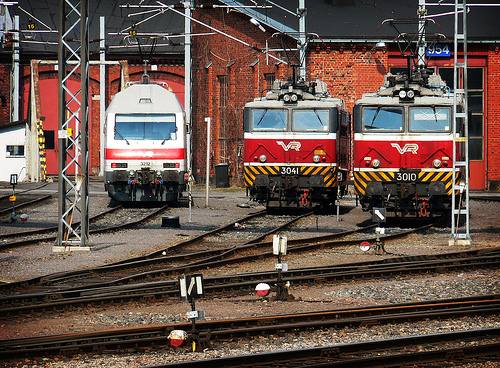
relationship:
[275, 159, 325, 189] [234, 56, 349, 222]
number on train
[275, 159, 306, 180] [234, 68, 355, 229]
number on train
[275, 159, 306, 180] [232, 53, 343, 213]
number on train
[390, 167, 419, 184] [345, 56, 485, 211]
number on train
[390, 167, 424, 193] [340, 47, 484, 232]
number on train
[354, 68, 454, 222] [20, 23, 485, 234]
engine in yard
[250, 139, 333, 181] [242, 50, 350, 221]
lights on train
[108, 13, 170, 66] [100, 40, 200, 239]
wires above train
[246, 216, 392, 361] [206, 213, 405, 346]
tracks on ground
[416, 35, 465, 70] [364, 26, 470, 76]
numbers on wall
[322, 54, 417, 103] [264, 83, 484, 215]
wall behind train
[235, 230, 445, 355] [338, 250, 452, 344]
gravel between tracks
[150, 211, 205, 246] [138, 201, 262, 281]
box on ground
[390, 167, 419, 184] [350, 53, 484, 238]
number on train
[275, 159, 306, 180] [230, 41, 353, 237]
number on train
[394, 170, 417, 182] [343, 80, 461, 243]
white number on train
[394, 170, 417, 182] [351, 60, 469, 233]
white number on train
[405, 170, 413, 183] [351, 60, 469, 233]
white number on train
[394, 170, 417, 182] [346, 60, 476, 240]
white number on train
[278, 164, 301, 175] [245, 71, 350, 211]
white number on train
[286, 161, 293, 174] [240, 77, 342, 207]
white number on train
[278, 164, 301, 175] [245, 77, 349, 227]
white number on train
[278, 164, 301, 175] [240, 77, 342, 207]
white number on train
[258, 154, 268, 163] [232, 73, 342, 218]
headlight on front of train car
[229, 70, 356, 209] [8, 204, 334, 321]
engine on train tracks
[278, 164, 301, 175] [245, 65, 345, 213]
white number on front of train car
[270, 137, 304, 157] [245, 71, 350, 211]
white letters on front of train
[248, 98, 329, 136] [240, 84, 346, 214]
windshield wipers on train car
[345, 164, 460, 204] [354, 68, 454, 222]
stripes on engine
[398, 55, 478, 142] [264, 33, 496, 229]
windows on brick building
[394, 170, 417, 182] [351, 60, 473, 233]
white number on front of train car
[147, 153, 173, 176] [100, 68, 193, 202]
black numbers on train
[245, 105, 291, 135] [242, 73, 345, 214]
window on train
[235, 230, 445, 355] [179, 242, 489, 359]
gravel on tracks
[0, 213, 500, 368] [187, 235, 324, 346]
ground railroad tracks with signals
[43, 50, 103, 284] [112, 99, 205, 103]
metal pole holding electrical wires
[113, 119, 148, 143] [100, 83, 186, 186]
window on front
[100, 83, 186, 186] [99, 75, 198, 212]
front on train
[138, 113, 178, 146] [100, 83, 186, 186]
window on front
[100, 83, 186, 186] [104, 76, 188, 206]
front on train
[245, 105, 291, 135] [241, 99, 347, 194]
window on front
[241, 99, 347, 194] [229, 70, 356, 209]
front on engine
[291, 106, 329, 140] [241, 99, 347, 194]
window on front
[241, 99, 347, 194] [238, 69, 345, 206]
front on train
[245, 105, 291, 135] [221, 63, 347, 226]
window on train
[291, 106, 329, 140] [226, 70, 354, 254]
window on train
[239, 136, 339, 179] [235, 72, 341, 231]
headlight in front of train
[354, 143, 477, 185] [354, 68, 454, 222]
headlight in front of engine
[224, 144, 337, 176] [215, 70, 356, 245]
frame on engine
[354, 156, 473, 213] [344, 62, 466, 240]
frame on engine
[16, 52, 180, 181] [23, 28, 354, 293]
door on building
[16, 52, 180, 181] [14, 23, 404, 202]
door on building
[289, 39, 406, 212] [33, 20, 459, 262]
door on building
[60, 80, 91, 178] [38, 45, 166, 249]
numbers over door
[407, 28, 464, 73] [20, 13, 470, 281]
sign on building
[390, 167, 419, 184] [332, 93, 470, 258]
number on trolley